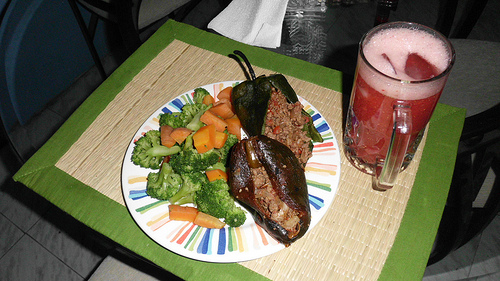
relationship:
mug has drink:
[344, 20, 454, 190] [350, 29, 448, 169]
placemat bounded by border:
[4, 16, 464, 278] [14, 19, 464, 278]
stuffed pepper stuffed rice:
[226, 45, 329, 164] [263, 80, 310, 163]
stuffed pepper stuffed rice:
[223, 132, 313, 248] [250, 168, 299, 235]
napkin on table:
[206, 0, 288, 49] [1, 0, 498, 280]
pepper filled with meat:
[225, 134, 312, 245] [250, 167, 297, 235]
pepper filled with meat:
[230, 48, 322, 165] [264, 86, 314, 168]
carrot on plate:
[192, 124, 216, 154] [121, 76, 340, 264]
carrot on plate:
[160, 87, 241, 229] [123, 66, 345, 269]